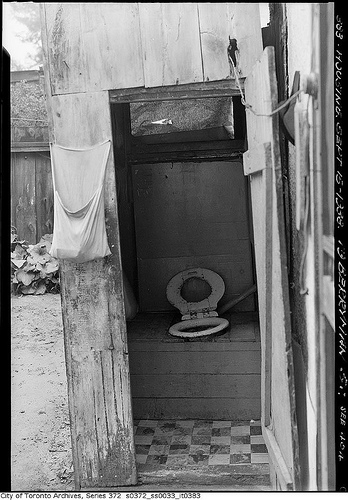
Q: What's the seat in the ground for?
A: Toilet.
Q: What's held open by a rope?
A: Door.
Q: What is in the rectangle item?
A: A toilet.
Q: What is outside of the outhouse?
A: A white bag.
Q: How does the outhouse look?
A: Very raggedy.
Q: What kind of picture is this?
A: An old photo.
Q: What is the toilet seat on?
A: A wooden box.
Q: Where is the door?
A: On the side.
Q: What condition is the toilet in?
A: A very old condition.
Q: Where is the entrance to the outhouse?
A: Directly in front.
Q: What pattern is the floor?
A: Checkerboard.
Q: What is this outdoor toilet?
A: Outhouse.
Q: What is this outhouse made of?
A: Wood.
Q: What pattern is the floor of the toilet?
A: Checkered.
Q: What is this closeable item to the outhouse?
A: Door.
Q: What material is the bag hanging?
A: Cotton.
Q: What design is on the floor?
A: Checkers.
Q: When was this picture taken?
A: Daytime.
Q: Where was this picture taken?
A: At an outhouse.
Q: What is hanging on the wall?
A: A bag.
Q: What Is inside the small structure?
A: A Toilet seat.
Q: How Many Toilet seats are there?
A: 1.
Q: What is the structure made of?
A: Wood.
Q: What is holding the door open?
A: A string.